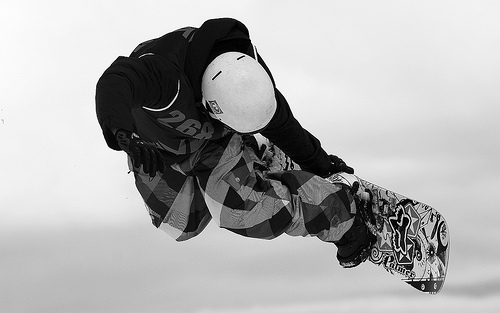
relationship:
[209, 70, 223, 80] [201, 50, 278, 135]
space on helmet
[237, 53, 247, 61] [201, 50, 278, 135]
space on helmet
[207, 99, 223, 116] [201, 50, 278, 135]
sticker on helmet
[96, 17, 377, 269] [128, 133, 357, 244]
person has pants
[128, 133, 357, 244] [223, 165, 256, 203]
pants have pocket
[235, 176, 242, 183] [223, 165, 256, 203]
button on pocket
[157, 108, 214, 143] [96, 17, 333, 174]
number on coat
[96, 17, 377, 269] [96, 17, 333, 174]
person has coat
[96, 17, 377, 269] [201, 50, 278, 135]
person wearing helmet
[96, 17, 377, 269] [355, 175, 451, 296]
person riding board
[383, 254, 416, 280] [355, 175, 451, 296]
word on board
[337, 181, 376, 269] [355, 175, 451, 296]
boot on board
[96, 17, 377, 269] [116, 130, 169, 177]
person wearing glove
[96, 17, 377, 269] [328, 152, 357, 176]
person wearing glove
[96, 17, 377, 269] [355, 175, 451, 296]
person grabbing board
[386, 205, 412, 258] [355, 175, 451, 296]
logo on board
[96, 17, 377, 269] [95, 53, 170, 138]
person has arm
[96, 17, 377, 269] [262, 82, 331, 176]
person has arm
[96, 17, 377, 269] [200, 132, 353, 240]
person has leg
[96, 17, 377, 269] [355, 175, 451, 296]
person has board